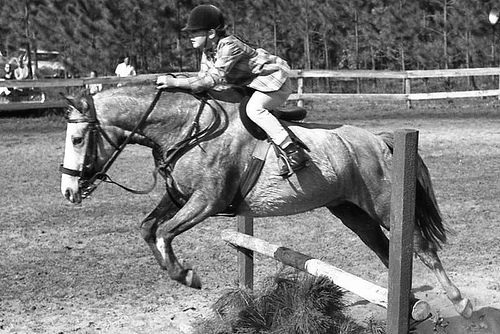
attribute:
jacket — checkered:
[187, 34, 292, 93]